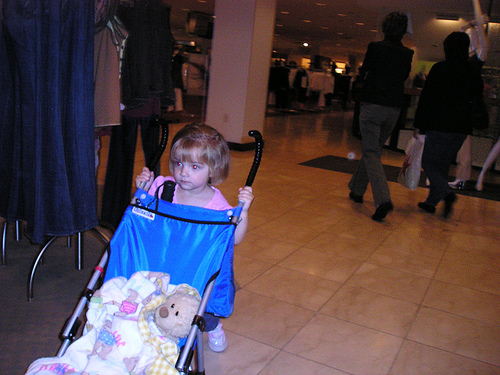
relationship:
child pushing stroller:
[135, 122, 257, 353] [47, 117, 273, 369]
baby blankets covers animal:
[25, 270, 202, 373] [154, 287, 203, 339]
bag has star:
[396, 123, 431, 194] [402, 154, 415, 175]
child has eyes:
[138, 121, 253, 357] [173, 160, 200, 172]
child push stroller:
[135, 122, 257, 353] [42, 104, 306, 373]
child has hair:
[135, 122, 257, 353] [163, 116, 249, 191]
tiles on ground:
[244, 225, 499, 363] [6, 128, 495, 373]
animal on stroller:
[103, 255, 185, 351] [23, 167, 257, 370]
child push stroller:
[135, 122, 257, 353] [47, 117, 273, 369]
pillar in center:
[206, 5, 272, 147] [183, 118, 273, 156]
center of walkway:
[183, 118, 273, 156] [13, 97, 488, 366]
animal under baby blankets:
[154, 287, 203, 339] [25, 270, 201, 375]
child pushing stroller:
[135, 122, 257, 353] [32, 115, 268, 373]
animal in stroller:
[154, 287, 203, 339] [32, 115, 268, 373]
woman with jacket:
[343, 18, 418, 225] [346, 41, 412, 105]